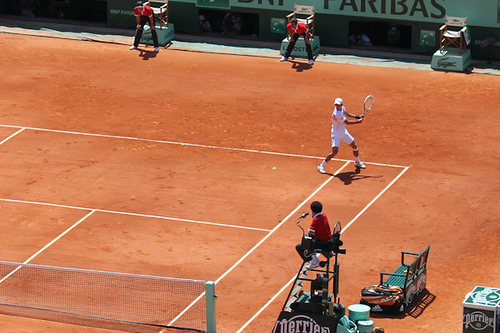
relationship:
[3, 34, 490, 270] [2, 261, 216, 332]
court has net